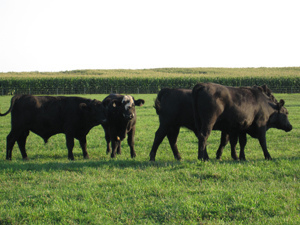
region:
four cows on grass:
[8, 85, 299, 175]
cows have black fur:
[167, 95, 263, 132]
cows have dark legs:
[219, 129, 261, 158]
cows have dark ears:
[263, 97, 297, 123]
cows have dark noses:
[285, 119, 290, 135]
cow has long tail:
[7, 97, 31, 127]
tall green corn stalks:
[15, 70, 297, 91]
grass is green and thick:
[131, 159, 275, 222]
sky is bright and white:
[99, 47, 207, 71]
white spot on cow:
[117, 97, 135, 109]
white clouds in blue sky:
[86, 1, 127, 49]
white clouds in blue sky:
[140, 14, 178, 56]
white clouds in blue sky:
[173, 10, 223, 53]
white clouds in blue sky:
[206, 21, 246, 54]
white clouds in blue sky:
[266, 13, 296, 49]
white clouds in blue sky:
[84, 18, 123, 63]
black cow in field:
[10, 82, 106, 163]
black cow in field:
[103, 90, 145, 147]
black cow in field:
[152, 83, 230, 155]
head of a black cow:
[273, 96, 294, 136]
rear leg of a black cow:
[194, 93, 214, 162]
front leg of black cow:
[256, 111, 274, 159]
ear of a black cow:
[134, 95, 145, 109]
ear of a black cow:
[277, 98, 285, 106]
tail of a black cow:
[1, 103, 12, 120]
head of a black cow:
[115, 95, 140, 136]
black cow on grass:
[187, 78, 292, 158]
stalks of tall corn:
[0, 64, 297, 94]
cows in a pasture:
[3, 61, 294, 223]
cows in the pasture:
[5, 77, 294, 182]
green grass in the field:
[92, 172, 297, 202]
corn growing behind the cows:
[24, 72, 175, 96]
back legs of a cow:
[143, 124, 191, 166]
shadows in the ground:
[24, 158, 184, 176]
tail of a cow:
[0, 93, 21, 121]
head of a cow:
[111, 113, 133, 147]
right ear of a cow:
[277, 94, 284, 106]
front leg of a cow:
[251, 132, 284, 174]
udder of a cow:
[34, 131, 57, 147]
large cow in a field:
[189, 79, 294, 162]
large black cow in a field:
[192, 80, 294, 161]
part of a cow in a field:
[150, 85, 229, 170]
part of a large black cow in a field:
[150, 83, 226, 162]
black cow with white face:
[99, 91, 144, 160]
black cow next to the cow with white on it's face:
[1, 92, 110, 157]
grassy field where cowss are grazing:
[0, 91, 299, 220]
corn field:
[1, 68, 298, 86]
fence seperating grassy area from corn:
[0, 86, 298, 95]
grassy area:
[198, 195, 257, 205]